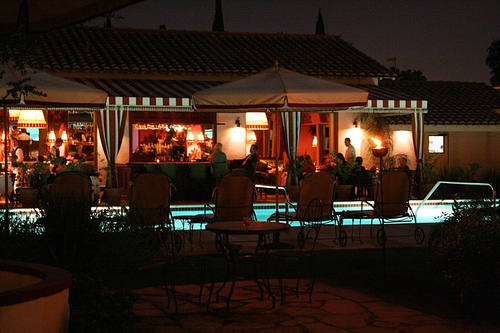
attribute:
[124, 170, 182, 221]
chair — in parts, in row, red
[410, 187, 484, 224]
pool — edged, sided, blue, outdoor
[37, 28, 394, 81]
roof — edged, brown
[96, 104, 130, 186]
curtain — in parts, long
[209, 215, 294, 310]
table — poolside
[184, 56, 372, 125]
umbrella — protective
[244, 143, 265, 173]
person — sitting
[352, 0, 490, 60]
sky — grey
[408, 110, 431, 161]
curtain — black, white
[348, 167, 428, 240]
chair — black, poolside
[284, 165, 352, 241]
chair — in parts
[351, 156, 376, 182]
person — sitting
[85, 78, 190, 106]
tent — in parts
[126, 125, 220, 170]
bar — outdoor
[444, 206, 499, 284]
bush — outdoor